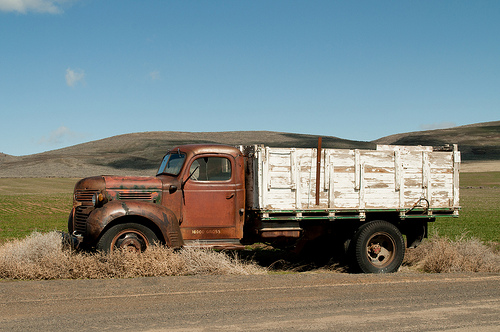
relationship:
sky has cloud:
[251, 39, 408, 101] [36, 121, 82, 151]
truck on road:
[71, 144, 460, 266] [0, 270, 499, 330]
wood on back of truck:
[300, 155, 414, 203] [243, 135, 462, 222]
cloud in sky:
[58, 54, 89, 94] [145, 27, 405, 107]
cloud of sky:
[2, 0, 67, 18] [1, 1, 496, 156]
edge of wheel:
[345, 247, 360, 271] [352, 218, 404, 274]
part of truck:
[185, 155, 243, 211] [71, 144, 460, 266]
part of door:
[189, 160, 229, 189] [178, 149, 238, 236]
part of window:
[166, 158, 186, 178] [205, 161, 232, 182]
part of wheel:
[368, 249, 384, 257] [350, 222, 405, 272]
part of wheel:
[370, 238, 410, 278] [348, 217, 405, 272]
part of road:
[283, 273, 388, 329] [0, 270, 499, 330]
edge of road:
[85, 283, 225, 291] [267, 269, 320, 296]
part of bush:
[35, 239, 55, 260] [0, 227, 270, 278]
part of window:
[198, 159, 245, 191] [155, 152, 185, 175]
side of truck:
[86, 188, 409, 218] [71, 144, 460, 266]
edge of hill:
[72, 140, 114, 171] [4, 126, 499, 177]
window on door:
[189, 154, 235, 185] [179, 146, 246, 239]